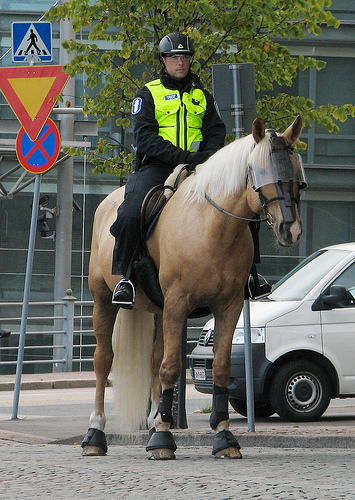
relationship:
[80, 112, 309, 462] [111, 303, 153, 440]
horse has tail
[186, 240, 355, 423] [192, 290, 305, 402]
van has front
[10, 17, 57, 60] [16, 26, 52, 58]
sign for pedestrian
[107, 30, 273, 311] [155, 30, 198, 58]
man wearing helmet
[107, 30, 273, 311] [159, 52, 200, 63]
man wearing glasses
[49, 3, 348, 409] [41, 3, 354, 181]
tree has leaves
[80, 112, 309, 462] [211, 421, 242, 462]
horse has foot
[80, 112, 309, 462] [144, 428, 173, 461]
horse has foot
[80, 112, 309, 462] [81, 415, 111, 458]
horse has foot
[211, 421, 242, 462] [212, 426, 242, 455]
foot has hoof cover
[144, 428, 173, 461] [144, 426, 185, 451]
foot has hoof cover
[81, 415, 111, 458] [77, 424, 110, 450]
foot has hoof cover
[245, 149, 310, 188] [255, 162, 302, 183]
visor on eyes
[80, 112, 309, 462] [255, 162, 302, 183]
horse has eyes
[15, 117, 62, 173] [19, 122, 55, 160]
sign has x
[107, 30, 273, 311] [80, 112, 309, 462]
man riding a horse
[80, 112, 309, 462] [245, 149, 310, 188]
horse wearing shield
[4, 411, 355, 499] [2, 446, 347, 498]
road made of bricks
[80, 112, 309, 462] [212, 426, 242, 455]
horse has hoof cover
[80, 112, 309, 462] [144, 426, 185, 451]
horse has hoof cover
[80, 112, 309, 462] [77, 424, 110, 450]
horse has hoof cover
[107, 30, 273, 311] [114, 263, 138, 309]
man has foot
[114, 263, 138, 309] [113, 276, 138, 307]
foot in a stirrup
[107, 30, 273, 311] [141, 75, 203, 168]
man wearing vest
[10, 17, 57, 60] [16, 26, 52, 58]
sign has pedestrian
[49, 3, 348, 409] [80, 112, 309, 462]
tree behind horse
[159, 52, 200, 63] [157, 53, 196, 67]
glasses are for safety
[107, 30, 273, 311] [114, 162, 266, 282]
man wearing pants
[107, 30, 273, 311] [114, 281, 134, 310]
man wearing shoes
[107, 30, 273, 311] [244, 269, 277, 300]
man wearing shoes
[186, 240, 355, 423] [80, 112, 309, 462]
van behind horse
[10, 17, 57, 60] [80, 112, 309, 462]
sign behind horse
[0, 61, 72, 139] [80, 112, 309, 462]
sign behind horse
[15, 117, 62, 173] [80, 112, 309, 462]
sign behind horse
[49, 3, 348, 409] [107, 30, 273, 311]
tree behind man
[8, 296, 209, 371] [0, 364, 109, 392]
fence on side of sidewalk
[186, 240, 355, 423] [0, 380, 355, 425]
van parked on street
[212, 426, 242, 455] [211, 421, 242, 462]
hoof cover on foot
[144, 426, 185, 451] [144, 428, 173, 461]
hoof cover on foot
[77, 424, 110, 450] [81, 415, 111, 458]
hoof cover on foot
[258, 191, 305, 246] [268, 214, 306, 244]
wraps are around shin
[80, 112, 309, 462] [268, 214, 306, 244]
horse has shin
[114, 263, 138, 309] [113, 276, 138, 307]
foot in stirrup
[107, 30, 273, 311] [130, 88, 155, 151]
man has sleeve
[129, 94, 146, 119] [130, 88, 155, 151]
patch on sleeve